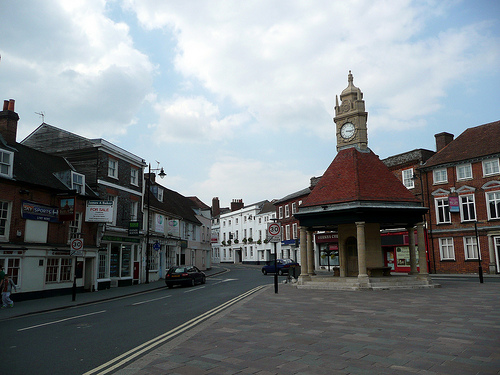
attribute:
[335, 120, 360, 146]
clock — white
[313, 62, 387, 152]
tower — small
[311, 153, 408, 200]
roof — red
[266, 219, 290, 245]
sign — white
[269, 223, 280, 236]
circle — red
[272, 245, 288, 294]
pole — black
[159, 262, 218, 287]
car — parked, dark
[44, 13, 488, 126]
sky — blue, cloudy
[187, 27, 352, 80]
clouds — white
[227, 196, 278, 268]
building — white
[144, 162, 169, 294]
light pole — tall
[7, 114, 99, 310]
building — brick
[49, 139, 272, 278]
buildings — three, grouped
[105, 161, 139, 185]
windows — white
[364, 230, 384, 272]
siding — wooden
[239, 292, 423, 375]
square — stone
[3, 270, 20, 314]
man — walking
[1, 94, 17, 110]
pipes — red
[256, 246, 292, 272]
car — blue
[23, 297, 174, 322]
line — white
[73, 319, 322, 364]
ground — gray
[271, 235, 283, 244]
letters — black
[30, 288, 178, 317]
lines — white